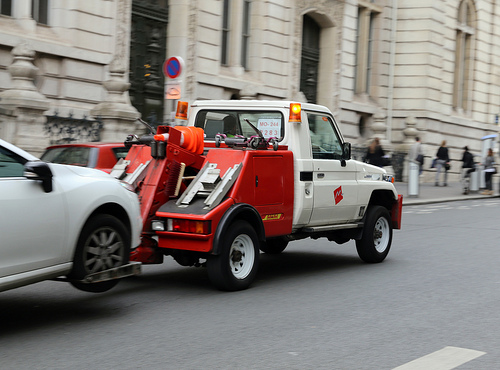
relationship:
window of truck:
[192, 108, 284, 141] [74, 62, 430, 307]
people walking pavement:
[376, 130, 498, 192] [390, 179, 499, 206]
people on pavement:
[426, 139, 453, 187] [387, 183, 499, 203]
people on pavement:
[406, 136, 426, 178] [387, 183, 499, 203]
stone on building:
[259, 26, 300, 39] [13, 6, 493, 177]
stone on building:
[414, 34, 442, 76] [33, 12, 473, 196]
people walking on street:
[426, 139, 453, 187] [0, 195, 497, 367]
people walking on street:
[461, 145, 478, 191] [0, 195, 497, 367]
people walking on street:
[406, 136, 426, 178] [0, 195, 497, 367]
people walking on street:
[365, 134, 390, 164] [0, 195, 497, 367]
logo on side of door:
[333, 184, 343, 203] [300, 106, 357, 228]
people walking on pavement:
[426, 139, 453, 187] [395, 183, 498, 206]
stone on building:
[193, 38, 220, 61] [54, 5, 481, 147]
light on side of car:
[280, 99, 305, 123] [137, 59, 444, 289]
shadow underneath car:
[0, 277, 157, 350] [0, 131, 150, 301]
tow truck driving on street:
[103, 92, 413, 287] [407, 204, 497, 367]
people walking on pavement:
[426, 139, 453, 187] [12, 169, 496, 368]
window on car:
[198, 110, 233, 140] [98, 98, 404, 292]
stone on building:
[257, 28, 293, 49] [13, 6, 493, 177]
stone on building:
[399, 32, 438, 41] [0, 0, 498, 97]